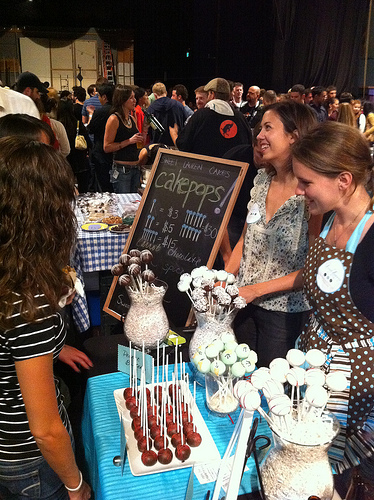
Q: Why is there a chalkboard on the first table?
A: To display the cost of the "cake pops.".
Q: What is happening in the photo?
A: At an event selling "cake pops".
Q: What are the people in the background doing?
A: Mingling.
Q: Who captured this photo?
A: A photographer.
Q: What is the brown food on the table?
A: Cake pops.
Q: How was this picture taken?
A: With a camera.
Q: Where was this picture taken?
A: At a food exhibition.